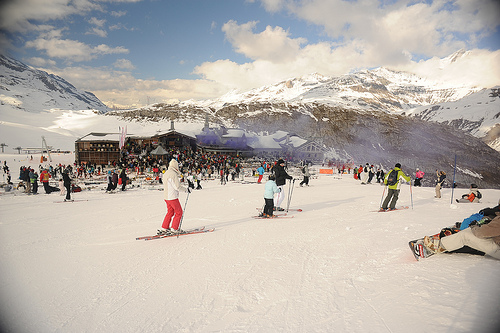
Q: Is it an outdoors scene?
A: Yes, it is outdoors.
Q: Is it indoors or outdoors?
A: It is outdoors.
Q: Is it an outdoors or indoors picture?
A: It is outdoors.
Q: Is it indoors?
A: No, it is outdoors.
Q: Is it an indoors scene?
A: No, it is outdoors.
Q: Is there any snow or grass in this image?
A: Yes, there is snow.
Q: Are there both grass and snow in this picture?
A: No, there is snow but no grass.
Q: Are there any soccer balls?
A: No, there are no soccer balls.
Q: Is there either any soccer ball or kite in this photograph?
A: No, there are no soccer balls or kites.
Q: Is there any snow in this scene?
A: Yes, there is snow.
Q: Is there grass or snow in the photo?
A: Yes, there is snow.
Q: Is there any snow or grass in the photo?
A: Yes, there is snow.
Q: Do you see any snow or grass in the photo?
A: Yes, there is snow.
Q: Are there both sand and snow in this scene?
A: No, there is snow but no sand.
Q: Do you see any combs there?
A: No, there are no combs.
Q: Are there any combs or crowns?
A: No, there are no combs or crowns.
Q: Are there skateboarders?
A: Yes, there is a skateboarder.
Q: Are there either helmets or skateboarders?
A: Yes, there is a skateboarder.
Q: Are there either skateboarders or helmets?
A: Yes, there is a skateboarder.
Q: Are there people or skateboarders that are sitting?
A: Yes, the skateboarder is sitting.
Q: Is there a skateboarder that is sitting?
A: Yes, there is a skateboarder that is sitting.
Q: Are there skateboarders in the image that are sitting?
A: Yes, there is a skateboarder that is sitting.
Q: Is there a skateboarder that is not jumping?
A: Yes, there is a skateboarder that is sitting.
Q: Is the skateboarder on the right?
A: Yes, the skateboarder is on the right of the image.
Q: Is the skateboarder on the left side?
A: No, the skateboarder is on the right of the image.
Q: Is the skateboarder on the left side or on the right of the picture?
A: The skateboarder is on the right of the image.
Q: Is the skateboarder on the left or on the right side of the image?
A: The skateboarder is on the right of the image.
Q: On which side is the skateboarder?
A: The skateboarder is on the right of the image.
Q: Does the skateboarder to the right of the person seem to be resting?
A: Yes, the skateboarder is resting.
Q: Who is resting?
A: The skateboarder is resting.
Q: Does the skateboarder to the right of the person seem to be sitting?
A: Yes, the skateboarder is sitting.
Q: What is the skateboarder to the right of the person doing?
A: The skateboarder is sitting.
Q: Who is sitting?
A: The skateboarder is sitting.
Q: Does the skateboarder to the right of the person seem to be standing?
A: No, the skateboarder is sitting.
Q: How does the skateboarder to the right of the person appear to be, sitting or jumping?
A: The skateboarder is sitting.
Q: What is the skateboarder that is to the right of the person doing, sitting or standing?
A: The skateboarder is sitting.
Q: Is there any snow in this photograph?
A: Yes, there is snow.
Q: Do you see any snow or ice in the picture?
A: Yes, there is snow.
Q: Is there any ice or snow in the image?
A: Yes, there is snow.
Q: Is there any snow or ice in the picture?
A: Yes, there is snow.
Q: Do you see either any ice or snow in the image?
A: Yes, there is snow.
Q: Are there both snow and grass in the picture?
A: No, there is snow but no grass.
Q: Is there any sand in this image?
A: No, there is no sand.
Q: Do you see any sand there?
A: No, there is no sand.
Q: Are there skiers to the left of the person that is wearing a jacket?
A: Yes, there is a skier to the left of the person.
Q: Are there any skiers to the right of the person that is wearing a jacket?
A: No, the skier is to the left of the person.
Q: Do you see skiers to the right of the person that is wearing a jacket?
A: No, the skier is to the left of the person.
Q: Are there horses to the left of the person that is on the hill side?
A: No, there is a skier to the left of the person.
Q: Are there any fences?
A: No, there are no fences.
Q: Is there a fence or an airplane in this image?
A: No, there are no fences or airplanes.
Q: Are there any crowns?
A: No, there are no crowns.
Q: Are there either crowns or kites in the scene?
A: No, there are no crowns or kites.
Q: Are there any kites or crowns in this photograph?
A: No, there are no crowns or kites.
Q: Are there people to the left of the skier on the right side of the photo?
A: Yes, there is a person to the left of the skier.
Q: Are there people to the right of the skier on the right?
A: No, the person is to the left of the skier.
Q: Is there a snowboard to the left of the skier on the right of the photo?
A: No, there is a person to the left of the skier.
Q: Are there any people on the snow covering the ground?
A: Yes, there is a person on the snow.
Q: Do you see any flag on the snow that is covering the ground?
A: No, there is a person on the snow.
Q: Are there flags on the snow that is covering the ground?
A: No, there is a person on the snow.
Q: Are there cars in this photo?
A: No, there are no cars.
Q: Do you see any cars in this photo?
A: No, there are no cars.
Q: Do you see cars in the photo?
A: No, there are no cars.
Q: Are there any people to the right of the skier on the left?
A: Yes, there is a person to the right of the skier.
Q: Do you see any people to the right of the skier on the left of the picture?
A: Yes, there is a person to the right of the skier.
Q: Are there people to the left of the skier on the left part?
A: No, the person is to the right of the skier.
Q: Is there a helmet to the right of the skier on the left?
A: No, there is a person to the right of the skier.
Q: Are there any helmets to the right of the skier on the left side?
A: No, there is a person to the right of the skier.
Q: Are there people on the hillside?
A: Yes, there is a person on the hillside.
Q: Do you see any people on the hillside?
A: Yes, there is a person on the hillside.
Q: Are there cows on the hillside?
A: No, there is a person on the hillside.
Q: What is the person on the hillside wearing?
A: The person is wearing a jacket.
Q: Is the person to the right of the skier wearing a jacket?
A: Yes, the person is wearing a jacket.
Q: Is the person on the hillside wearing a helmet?
A: No, the person is wearing a jacket.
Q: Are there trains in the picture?
A: No, there are no trains.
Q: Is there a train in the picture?
A: No, there are no trains.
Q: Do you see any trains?
A: No, there are no trains.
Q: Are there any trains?
A: No, there are no trains.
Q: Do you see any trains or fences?
A: No, there are no trains or fences.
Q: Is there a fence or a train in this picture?
A: No, there are no trains or fences.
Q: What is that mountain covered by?
A: The mountain is covered by the snow.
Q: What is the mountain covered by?
A: The mountain is covered by the snow.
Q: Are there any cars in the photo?
A: No, there are no cars.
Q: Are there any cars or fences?
A: No, there are no cars or fences.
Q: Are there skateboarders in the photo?
A: Yes, there is a skateboarder.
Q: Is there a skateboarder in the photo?
A: Yes, there is a skateboarder.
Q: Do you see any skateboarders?
A: Yes, there is a skateboarder.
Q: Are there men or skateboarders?
A: Yes, there is a skateboarder.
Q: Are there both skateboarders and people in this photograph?
A: Yes, there are both a skateboarder and people.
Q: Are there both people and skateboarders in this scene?
A: Yes, there are both a skateboarder and people.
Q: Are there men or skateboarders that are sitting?
A: Yes, the skateboarder is sitting.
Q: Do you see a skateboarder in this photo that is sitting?
A: Yes, there is a skateboarder that is sitting.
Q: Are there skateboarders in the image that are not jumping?
A: Yes, there is a skateboarder that is sitting.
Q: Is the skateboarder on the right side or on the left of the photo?
A: The skateboarder is on the right of the image.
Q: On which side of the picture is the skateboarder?
A: The skateboarder is on the right of the image.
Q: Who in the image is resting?
A: The skateboarder is resting.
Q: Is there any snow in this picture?
A: Yes, there is snow.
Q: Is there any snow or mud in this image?
A: Yes, there is snow.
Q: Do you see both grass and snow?
A: No, there is snow but no grass.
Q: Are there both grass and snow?
A: No, there is snow but no grass.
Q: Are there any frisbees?
A: No, there are no frisbees.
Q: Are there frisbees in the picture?
A: No, there are no frisbees.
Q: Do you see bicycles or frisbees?
A: No, there are no frisbees or bicycles.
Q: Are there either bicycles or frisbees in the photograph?
A: No, there are no frisbees or bicycles.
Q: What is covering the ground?
A: The snow is covering the ground.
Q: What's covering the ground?
A: The snow is covering the ground.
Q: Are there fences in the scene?
A: No, there are no fences.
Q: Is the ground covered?
A: Yes, the ground is covered.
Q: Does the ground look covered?
A: Yes, the ground is covered.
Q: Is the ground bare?
A: No, the ground is covered.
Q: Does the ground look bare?
A: No, the ground is covered.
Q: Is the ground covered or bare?
A: The ground is covered.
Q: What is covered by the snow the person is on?
A: The ground is covered by the snow.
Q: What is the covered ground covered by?
A: The ground is covered by the snow.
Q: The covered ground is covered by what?
A: The ground is covered by the snow.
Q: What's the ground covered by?
A: The ground is covered by the snow.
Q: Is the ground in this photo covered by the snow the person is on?
A: Yes, the ground is covered by the snow.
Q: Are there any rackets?
A: No, there are no rackets.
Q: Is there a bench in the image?
A: No, there are no benches.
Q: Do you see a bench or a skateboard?
A: No, there are no benches or skateboards.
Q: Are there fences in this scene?
A: No, there are no fences.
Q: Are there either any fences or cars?
A: No, there are no fences or cars.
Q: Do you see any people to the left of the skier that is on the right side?
A: Yes, there is a person to the left of the skier.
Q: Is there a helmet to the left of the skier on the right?
A: No, there is a person to the left of the skier.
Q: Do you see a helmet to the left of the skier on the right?
A: No, there is a person to the left of the skier.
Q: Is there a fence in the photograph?
A: No, there are no fences.